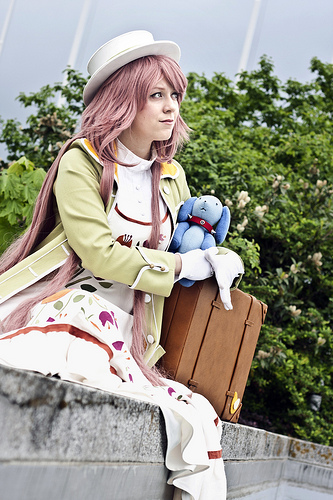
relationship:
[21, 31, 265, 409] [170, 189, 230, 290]
girl has animal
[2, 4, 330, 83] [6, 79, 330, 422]
sky above trees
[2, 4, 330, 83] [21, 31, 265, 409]
sky above girl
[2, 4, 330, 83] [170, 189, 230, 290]
sky above animal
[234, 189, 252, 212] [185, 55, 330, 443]
flowers on bush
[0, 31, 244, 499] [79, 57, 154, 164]
girl with hair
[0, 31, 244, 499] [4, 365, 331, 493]
girl sitting on wall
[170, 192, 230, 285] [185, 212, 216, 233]
animal with collar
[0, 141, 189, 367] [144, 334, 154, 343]
coat with buttons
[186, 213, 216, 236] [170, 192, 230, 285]
collar on animal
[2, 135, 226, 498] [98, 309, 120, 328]
dress with flowers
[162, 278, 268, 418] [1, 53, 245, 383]
suitcase next to girl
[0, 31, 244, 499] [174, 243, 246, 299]
girl wearing gloves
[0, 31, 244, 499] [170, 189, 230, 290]
girl holding animal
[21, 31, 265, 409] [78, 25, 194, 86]
girl wearing hat